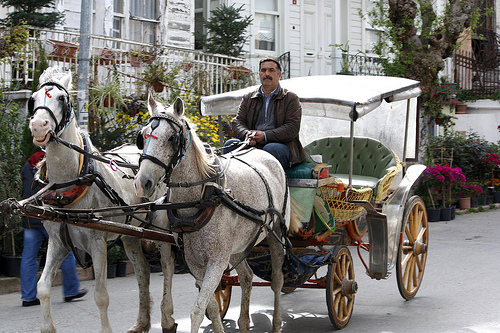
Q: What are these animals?
A: Horses.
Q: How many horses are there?
A: 2.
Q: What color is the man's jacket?
A: Brown.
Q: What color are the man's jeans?
A: Blue.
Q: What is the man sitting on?
A: Cart.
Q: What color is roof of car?
A: White.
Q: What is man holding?
A: Straps.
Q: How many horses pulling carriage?
A: Two.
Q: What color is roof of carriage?
A: White.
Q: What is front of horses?
A: Pole.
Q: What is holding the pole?
A: Strap.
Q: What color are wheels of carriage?
A: Orange and black.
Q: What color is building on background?
A: White.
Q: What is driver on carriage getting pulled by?
A: Horses.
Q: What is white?
A: Horses.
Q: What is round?
A: Wheels.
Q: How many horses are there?
A: Two.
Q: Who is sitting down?
A: A man.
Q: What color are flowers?
A: Pink.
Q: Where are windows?
A: On a house.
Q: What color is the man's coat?
A: Brown.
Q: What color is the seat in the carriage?
A: Green.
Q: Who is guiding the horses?
A: A man.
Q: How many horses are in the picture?
A: 2.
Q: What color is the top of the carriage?
A: White.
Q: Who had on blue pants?
A: The man walking.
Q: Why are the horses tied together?
A: To pull the carriage.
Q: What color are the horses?
A: White.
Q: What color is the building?
A: White.